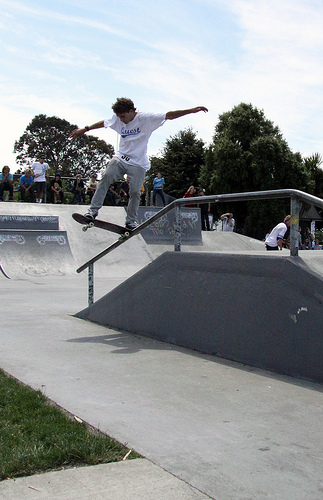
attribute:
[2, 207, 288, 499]
skateboarding park — silver, cemented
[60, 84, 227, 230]
one boy — grinding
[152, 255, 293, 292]
part of a line — cement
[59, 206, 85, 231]
edge of a skateboard — wooden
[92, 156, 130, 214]
part of a trouser — white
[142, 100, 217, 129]
left hand — extended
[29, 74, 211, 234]
skater doing a trick — caucasian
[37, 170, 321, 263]
grinding on a rail — skateboarder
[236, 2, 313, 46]
clouds — white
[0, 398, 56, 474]
grass — green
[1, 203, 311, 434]
skate park — grey color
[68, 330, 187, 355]
shadow — dark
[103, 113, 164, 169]
shirt — white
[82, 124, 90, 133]
watch — black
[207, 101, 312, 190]
trees — green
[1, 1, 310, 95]
sky — blue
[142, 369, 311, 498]
sidewalk — cement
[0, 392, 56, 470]
grass — green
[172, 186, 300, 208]
railing — metal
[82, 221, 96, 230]
wheels — polyurethane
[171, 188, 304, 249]
railing — metal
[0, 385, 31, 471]
grass — green